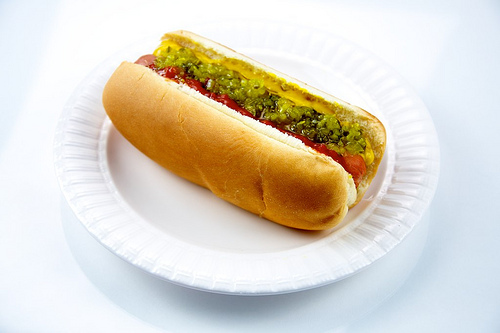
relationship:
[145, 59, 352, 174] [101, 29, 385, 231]
ketchup on hot dog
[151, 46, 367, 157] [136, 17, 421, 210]
mustard on hot dog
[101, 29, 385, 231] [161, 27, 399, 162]
hot dog with mustard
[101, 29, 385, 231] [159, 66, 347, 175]
hot dog with ketchup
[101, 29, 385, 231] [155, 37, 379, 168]
hot dog with relish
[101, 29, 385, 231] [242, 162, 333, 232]
hot dog in bun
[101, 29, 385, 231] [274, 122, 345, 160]
hot dog with ketchup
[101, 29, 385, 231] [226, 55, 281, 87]
hot dog with mustard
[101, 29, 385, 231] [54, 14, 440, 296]
hot dog on paper plate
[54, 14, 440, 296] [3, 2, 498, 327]
paper plate on table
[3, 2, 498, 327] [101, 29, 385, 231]
table with hot dog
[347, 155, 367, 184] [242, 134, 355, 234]
hotdog in bun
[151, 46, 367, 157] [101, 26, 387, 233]
mustard on bun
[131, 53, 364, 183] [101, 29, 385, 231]
hot dog on hot dog